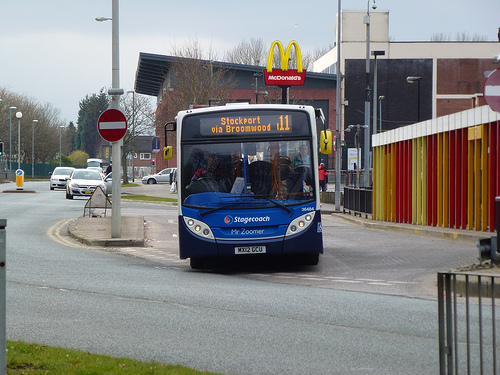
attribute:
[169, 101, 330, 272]
bus — blue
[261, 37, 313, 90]
sign — yellow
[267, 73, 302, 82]
mcdonald — yellow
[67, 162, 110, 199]
car — white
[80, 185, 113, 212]
sign — triangular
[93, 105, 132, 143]
sign — round, red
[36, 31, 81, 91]
sky — white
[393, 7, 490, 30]
sky — baby blue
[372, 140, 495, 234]
wall — multi-colored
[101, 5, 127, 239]
pole — tall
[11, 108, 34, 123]
lamp — off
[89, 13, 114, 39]
streetlight — off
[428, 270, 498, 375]
fence — metal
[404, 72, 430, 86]
streetlight — off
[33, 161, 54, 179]
fence — green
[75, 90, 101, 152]
tree — green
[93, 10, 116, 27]
streetlight — gray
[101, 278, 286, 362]
street — gray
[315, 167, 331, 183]
jacket — red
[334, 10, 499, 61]
roof — white